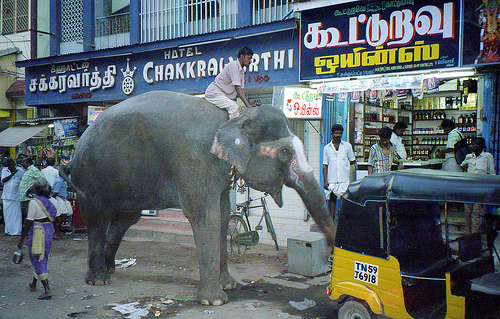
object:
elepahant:
[58, 90, 337, 306]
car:
[325, 167, 499, 318]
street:
[0, 228, 352, 317]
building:
[0, 0, 499, 319]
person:
[40, 157, 59, 189]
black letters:
[354, 262, 377, 283]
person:
[438, 119, 464, 213]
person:
[18, 157, 46, 239]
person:
[50, 165, 70, 239]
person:
[460, 137, 496, 235]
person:
[322, 124, 355, 222]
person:
[17, 177, 61, 299]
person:
[368, 126, 405, 175]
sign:
[354, 260, 379, 285]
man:
[205, 46, 258, 120]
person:
[389, 121, 407, 161]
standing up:
[308, 151, 353, 242]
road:
[0, 231, 340, 318]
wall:
[0, 1, 499, 236]